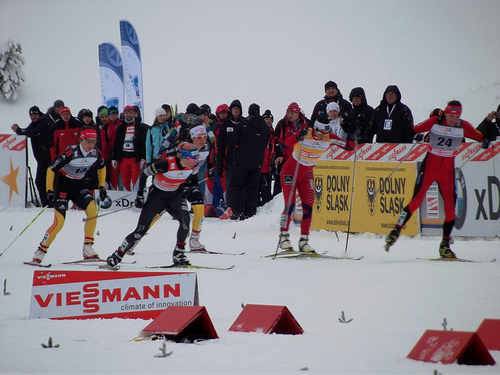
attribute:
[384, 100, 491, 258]
person — competing, skiing, racing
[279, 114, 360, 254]
person — competing, skiing, racing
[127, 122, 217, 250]
person — competing, skiing, racing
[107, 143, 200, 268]
person — competing, skiing, racing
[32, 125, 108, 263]
person — competing, skiing, racing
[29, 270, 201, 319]
sign — white, red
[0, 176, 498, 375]
snow — white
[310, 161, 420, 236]
sign — yellow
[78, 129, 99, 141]
headband — red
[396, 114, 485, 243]
ski suit — red, white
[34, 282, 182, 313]
lettering — red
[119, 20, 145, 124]
banner — blue, white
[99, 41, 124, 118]
banner — blue, white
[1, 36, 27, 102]
tree — snow covered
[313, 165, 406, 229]
lettering — black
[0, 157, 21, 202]
star — yellow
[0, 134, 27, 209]
sign — white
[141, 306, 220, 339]
sign — red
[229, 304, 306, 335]
sign — red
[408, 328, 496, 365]
sign — red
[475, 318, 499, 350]
sign — red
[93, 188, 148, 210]
sign — white, bmw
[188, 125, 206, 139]
headband — white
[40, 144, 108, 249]
ski suit — yellow, black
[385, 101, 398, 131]
lanyard — white